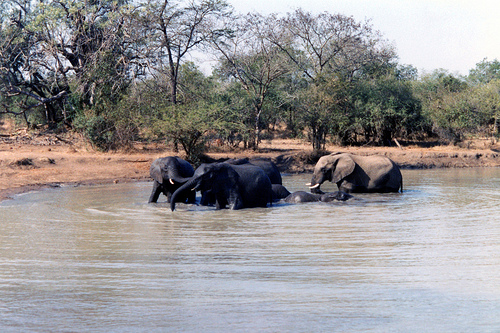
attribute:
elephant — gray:
[305, 151, 405, 196]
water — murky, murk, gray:
[3, 213, 500, 332]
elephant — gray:
[172, 164, 274, 212]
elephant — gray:
[147, 157, 193, 208]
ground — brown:
[3, 156, 147, 197]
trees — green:
[0, 2, 499, 137]